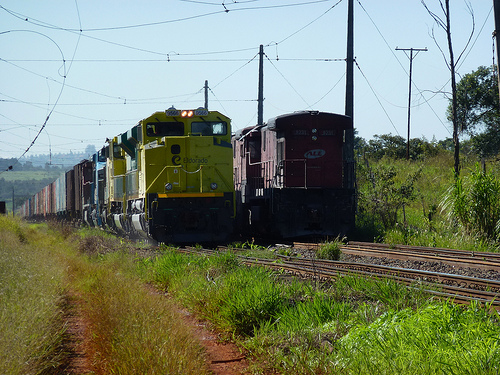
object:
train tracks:
[290, 241, 500, 273]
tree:
[446, 66, 500, 165]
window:
[191, 121, 227, 136]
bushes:
[353, 132, 499, 231]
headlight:
[210, 182, 218, 190]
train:
[20, 104, 238, 246]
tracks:
[166, 245, 500, 315]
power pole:
[257, 44, 264, 124]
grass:
[127, 249, 499, 375]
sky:
[1, 0, 498, 162]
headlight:
[165, 183, 172, 191]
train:
[231, 110, 353, 240]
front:
[141, 104, 234, 245]